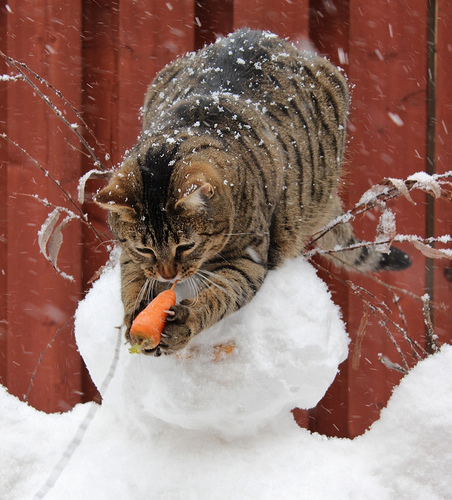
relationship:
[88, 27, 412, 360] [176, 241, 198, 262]
cat has eye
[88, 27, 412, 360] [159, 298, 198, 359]
cat has paw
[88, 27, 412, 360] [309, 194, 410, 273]
cat has tail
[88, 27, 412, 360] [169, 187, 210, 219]
cat has ear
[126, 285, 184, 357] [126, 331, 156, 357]
carrot has top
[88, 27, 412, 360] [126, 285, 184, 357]
cat has carrot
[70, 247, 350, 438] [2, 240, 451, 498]
snowball on snowman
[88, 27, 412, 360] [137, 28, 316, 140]
cat has back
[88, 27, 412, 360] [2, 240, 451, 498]
cat on snowman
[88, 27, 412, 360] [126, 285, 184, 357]
cat eating carrot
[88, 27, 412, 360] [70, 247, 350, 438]
cat in snowball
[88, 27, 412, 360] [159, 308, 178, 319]
cat has claw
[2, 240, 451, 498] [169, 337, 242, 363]
snowman has mouth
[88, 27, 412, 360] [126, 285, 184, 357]
cat holding carrot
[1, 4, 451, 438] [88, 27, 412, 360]
wall behind cat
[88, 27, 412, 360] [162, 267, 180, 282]
cat has nose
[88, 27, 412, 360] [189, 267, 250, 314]
cat has whiskers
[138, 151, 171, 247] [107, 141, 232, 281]
stripe on head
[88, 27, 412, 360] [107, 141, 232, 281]
cat has head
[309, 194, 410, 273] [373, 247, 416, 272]
tail has tip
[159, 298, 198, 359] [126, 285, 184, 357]
paw holding carrot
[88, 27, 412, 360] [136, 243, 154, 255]
cat has left eye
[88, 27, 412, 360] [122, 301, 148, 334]
cat has left paw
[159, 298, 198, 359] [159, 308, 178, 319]
paw has claw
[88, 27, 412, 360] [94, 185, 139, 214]
cat has left ear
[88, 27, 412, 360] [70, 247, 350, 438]
cat on snowball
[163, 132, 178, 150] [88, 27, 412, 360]
snow on cat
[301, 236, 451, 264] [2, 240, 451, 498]
branch in snowman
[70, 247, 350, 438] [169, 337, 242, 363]
snowball has mouth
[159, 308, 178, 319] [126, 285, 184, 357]
claw in carrot